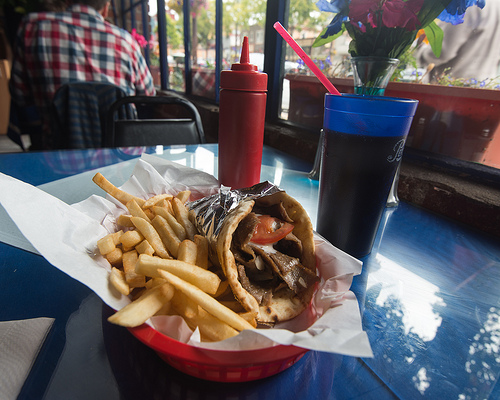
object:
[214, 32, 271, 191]
bottle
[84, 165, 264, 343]
fries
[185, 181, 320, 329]
gyro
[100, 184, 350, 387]
container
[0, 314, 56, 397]
napkin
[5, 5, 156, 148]
shirt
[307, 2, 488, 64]
flowers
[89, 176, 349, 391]
basket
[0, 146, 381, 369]
paper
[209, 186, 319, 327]
tortilla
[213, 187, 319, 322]
bread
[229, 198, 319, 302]
meat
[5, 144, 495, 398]
table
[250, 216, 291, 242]
sliced tomato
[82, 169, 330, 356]
food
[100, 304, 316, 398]
plate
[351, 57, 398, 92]
flower vase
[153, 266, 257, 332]
french fry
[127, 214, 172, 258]
french fry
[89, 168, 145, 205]
french fry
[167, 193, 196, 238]
french fry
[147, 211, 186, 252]
french fry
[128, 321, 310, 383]
basket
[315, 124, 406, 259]
soda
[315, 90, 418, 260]
cup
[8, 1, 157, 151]
man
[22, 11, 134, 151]
back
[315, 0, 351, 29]
flower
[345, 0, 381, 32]
flower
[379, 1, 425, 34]
flower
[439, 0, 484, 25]
flower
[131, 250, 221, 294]
fry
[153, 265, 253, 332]
fry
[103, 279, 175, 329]
fry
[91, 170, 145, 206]
fry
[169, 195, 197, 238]
fry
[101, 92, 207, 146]
chair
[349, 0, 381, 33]
flower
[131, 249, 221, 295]
french fry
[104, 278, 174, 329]
french fry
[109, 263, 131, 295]
french fry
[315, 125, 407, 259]
pepsi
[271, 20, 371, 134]
drinking straw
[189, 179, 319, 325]
wrap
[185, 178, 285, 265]
foil